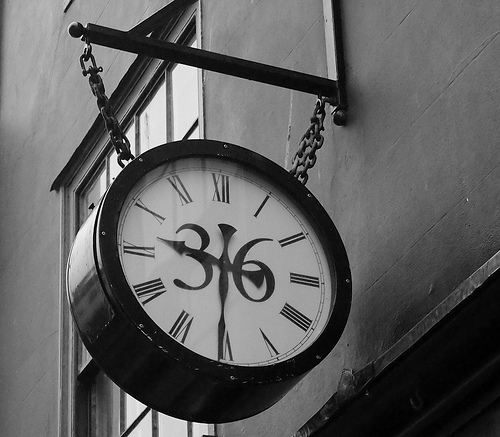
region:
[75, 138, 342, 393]
Clock being held up by chains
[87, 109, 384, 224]
Clock being held up by chains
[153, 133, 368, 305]
Clock being held up by chains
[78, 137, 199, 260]
Clock being held up by chains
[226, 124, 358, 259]
Clock being held up by chains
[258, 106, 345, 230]
Clock being held up by chains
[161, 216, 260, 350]
clock's hands are black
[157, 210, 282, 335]
the number is 36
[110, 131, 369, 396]
Clock hanging on chains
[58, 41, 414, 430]
Clock hanging on chains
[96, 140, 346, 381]
Clock hanging on the building.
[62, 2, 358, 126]
Black metal bracket holding clock.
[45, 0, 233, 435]
Window in the building.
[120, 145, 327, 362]
Black roman numerals on the clock.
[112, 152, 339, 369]
White face on the clock.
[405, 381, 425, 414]
Metal hook in the wood.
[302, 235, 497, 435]
Wood board on side of building.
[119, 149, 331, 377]
Clear glass on the clock.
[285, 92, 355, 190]
Black chain attached to clock.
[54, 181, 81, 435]
Wooden wood frame on side of window.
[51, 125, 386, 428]
clock on a bulding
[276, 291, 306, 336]
number on a clock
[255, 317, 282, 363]
number on a clock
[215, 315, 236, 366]
number on a clock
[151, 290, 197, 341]
number on a clock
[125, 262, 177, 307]
number on a clock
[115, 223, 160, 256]
number on a clock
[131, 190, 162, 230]
number on a clock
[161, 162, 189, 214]
number on a clock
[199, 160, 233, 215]
number on a clock